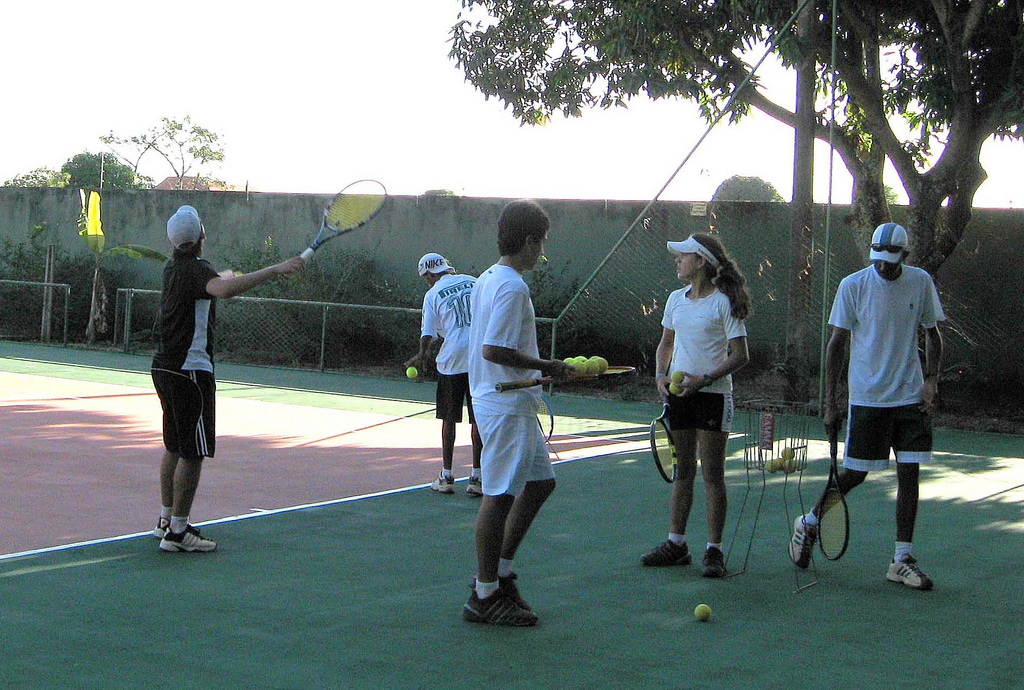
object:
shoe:
[885, 554, 934, 589]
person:
[785, 221, 947, 593]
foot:
[885, 553, 935, 590]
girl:
[636, 231, 753, 580]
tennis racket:
[649, 382, 681, 484]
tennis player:
[402, 251, 485, 496]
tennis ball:
[670, 370, 686, 385]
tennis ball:
[573, 355, 589, 362]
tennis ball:
[588, 355, 599, 361]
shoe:
[151, 516, 200, 539]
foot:
[158, 522, 221, 554]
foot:
[462, 582, 542, 627]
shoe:
[462, 586, 541, 626]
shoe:
[466, 570, 532, 612]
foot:
[466, 569, 531, 613]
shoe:
[701, 545, 726, 577]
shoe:
[158, 527, 219, 554]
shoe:
[430, 469, 455, 493]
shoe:
[466, 475, 483, 496]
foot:
[429, 468, 456, 495]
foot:
[466, 476, 483, 496]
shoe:
[640, 537, 694, 566]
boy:
[148, 204, 309, 553]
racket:
[495, 365, 638, 394]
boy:
[460, 199, 580, 630]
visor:
[666, 234, 720, 269]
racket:
[301, 178, 388, 262]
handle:
[299, 244, 319, 265]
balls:
[781, 447, 797, 460]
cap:
[870, 222, 909, 266]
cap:
[417, 252, 456, 277]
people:
[147, 201, 949, 630]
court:
[0, 338, 1024, 689]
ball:
[693, 603, 713, 622]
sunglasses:
[870, 242, 903, 253]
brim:
[866, 246, 904, 264]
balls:
[570, 360, 586, 374]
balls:
[766, 460, 780, 473]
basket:
[744, 396, 816, 475]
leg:
[788, 417, 887, 569]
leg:
[695, 396, 730, 578]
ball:
[405, 366, 418, 379]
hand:
[403, 349, 431, 372]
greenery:
[0, 253, 1024, 423]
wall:
[0, 183, 1024, 427]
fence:
[0, 148, 1024, 435]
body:
[148, 254, 217, 522]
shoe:
[788, 512, 820, 569]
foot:
[788, 513, 821, 569]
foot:
[701, 544, 728, 579]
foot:
[638, 532, 693, 566]